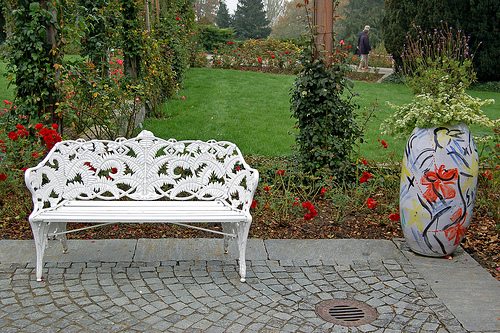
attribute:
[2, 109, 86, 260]
bush — red, rose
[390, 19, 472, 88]
flowers — purple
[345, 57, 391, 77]
walkway — cement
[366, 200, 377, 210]
flowers — red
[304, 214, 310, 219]
flowers — red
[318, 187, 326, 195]
flowers — red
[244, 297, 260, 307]
bricks — gray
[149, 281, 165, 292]
bricks — gray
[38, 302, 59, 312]
bricks — gray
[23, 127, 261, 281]
bench — white